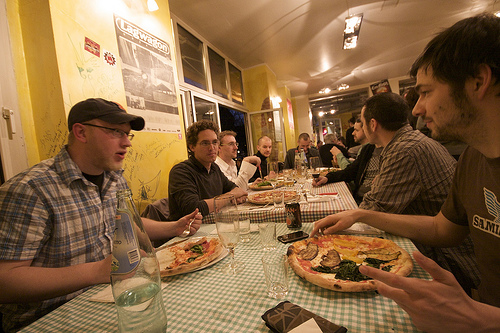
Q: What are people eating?
A: Pizza.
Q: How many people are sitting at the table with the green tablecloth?
A: Two.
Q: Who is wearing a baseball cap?
A: The man wearing a plaid shirt.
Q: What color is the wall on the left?
A: Yellow.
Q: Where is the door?
A: On the left hand side after the last table.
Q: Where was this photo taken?
A: In a restaurant.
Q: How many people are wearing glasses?
A: Three.